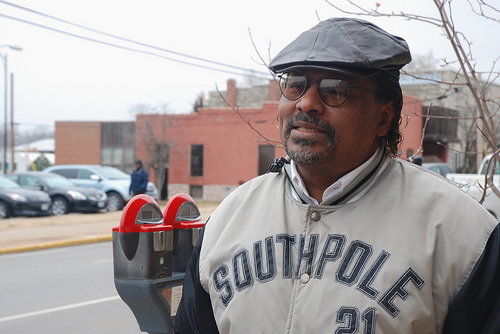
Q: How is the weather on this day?
A: It is clear.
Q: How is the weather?
A: It is clear.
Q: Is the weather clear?
A: Yes, it is clear.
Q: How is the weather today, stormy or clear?
A: It is clear.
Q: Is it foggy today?
A: No, it is clear.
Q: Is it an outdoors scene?
A: Yes, it is outdoors.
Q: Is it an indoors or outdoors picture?
A: It is outdoors.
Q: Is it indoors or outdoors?
A: It is outdoors.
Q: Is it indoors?
A: No, it is outdoors.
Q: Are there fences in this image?
A: No, there are no fences.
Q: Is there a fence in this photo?
A: No, there are no fences.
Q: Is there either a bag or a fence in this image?
A: No, there are no fences or bags.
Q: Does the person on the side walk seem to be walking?
A: Yes, the person is walking.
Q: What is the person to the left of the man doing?
A: The person is walking.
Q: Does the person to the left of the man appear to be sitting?
A: No, the person is walking.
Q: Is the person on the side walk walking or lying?
A: The person is walking.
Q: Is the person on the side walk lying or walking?
A: The person is walking.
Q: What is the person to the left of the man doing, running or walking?
A: The person is walking.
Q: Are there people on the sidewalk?
A: Yes, there is a person on the sidewalk.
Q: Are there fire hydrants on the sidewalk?
A: No, there is a person on the sidewalk.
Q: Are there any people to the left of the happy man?
A: Yes, there is a person to the left of the man.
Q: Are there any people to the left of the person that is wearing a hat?
A: Yes, there is a person to the left of the man.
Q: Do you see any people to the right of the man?
A: No, the person is to the left of the man.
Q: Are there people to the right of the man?
A: No, the person is to the left of the man.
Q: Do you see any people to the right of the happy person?
A: No, the person is to the left of the man.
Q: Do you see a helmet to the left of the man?
A: No, there is a person to the left of the man.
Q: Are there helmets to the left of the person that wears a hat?
A: No, there is a person to the left of the man.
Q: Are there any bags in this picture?
A: No, there are no bags.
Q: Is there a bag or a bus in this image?
A: No, there are no bags or buses.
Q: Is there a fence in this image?
A: No, there are no fences.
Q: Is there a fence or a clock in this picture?
A: No, there are no fences or clocks.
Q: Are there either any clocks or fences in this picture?
A: No, there are no fences or clocks.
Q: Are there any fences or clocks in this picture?
A: No, there are no fences or clocks.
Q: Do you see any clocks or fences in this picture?
A: No, there are no fences or clocks.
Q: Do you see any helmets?
A: No, there are no helmets.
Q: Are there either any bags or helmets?
A: No, there are no helmets or bags.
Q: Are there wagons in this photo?
A: No, there are no wagons.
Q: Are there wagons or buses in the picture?
A: No, there are no wagons or buses.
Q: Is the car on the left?
A: Yes, the car is on the left of the image.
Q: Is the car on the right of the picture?
A: No, the car is on the left of the image.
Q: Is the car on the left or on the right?
A: The car is on the left of the image.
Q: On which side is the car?
A: The car is on the left of the image.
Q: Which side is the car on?
A: The car is on the left of the image.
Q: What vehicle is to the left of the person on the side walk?
A: The vehicle is a car.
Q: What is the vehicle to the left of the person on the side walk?
A: The vehicle is a car.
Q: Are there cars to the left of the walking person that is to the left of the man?
A: Yes, there is a car to the left of the person.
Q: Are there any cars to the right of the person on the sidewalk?
A: No, the car is to the left of the person.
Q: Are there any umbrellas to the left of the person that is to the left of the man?
A: No, there is a car to the left of the person.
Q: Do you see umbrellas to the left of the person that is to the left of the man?
A: No, there is a car to the left of the person.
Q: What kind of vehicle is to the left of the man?
A: The vehicle is a car.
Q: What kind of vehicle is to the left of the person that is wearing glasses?
A: The vehicle is a car.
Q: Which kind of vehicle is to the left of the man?
A: The vehicle is a car.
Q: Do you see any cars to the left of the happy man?
A: Yes, there is a car to the left of the man.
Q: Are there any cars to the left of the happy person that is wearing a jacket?
A: Yes, there is a car to the left of the man.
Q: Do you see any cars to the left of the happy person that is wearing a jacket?
A: Yes, there is a car to the left of the man.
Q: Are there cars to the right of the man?
A: No, the car is to the left of the man.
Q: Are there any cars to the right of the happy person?
A: No, the car is to the left of the man.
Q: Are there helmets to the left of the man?
A: No, there is a car to the left of the man.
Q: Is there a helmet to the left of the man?
A: No, there is a car to the left of the man.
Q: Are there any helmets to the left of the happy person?
A: No, there is a car to the left of the man.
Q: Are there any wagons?
A: No, there are no wagons.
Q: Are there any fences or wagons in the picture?
A: No, there are no wagons or fences.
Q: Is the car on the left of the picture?
A: Yes, the car is on the left of the image.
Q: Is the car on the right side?
A: No, the car is on the left of the image.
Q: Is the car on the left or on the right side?
A: The car is on the left of the image.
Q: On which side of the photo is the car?
A: The car is on the left of the image.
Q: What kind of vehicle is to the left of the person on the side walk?
A: The vehicle is a car.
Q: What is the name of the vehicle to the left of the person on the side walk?
A: The vehicle is a car.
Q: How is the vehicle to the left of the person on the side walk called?
A: The vehicle is a car.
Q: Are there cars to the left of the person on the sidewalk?
A: Yes, there is a car to the left of the person.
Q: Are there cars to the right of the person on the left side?
A: No, the car is to the left of the person.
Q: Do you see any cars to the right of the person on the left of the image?
A: No, the car is to the left of the person.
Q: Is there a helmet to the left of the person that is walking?
A: No, there is a car to the left of the person.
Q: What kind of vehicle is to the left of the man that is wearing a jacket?
A: The vehicle is a car.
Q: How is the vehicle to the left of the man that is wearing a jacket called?
A: The vehicle is a car.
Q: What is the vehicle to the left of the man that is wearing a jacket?
A: The vehicle is a car.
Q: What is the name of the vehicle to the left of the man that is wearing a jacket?
A: The vehicle is a car.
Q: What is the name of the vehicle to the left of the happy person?
A: The vehicle is a car.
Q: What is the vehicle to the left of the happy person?
A: The vehicle is a car.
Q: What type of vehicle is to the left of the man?
A: The vehicle is a car.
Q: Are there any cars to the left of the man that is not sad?
A: Yes, there is a car to the left of the man.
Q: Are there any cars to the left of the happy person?
A: Yes, there is a car to the left of the man.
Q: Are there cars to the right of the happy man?
A: No, the car is to the left of the man.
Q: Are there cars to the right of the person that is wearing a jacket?
A: No, the car is to the left of the man.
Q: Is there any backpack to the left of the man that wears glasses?
A: No, there is a car to the left of the man.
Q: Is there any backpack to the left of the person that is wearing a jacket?
A: No, there is a car to the left of the man.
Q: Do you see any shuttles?
A: No, there are no shuttles.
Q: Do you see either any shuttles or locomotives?
A: No, there are no shuttles or locomotives.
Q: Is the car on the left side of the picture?
A: Yes, the car is on the left of the image.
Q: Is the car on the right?
A: No, the car is on the left of the image.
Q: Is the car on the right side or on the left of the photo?
A: The car is on the left of the image.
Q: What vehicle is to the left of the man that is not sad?
A: The vehicle is a car.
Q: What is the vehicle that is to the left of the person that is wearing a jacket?
A: The vehicle is a car.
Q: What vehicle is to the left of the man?
A: The vehicle is a car.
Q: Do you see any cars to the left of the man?
A: Yes, there is a car to the left of the man.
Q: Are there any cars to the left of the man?
A: Yes, there is a car to the left of the man.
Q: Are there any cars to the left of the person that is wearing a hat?
A: Yes, there is a car to the left of the man.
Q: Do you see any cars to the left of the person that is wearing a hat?
A: Yes, there is a car to the left of the man.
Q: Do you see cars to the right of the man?
A: No, the car is to the left of the man.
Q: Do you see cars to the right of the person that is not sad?
A: No, the car is to the left of the man.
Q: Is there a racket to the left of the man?
A: No, there is a car to the left of the man.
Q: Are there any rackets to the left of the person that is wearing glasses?
A: No, there is a car to the left of the man.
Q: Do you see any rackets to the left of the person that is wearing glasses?
A: No, there is a car to the left of the man.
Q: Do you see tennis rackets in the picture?
A: No, there are no tennis rackets.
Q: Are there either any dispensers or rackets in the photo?
A: No, there are no rackets or dispensers.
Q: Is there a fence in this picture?
A: No, there are no fences.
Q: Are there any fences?
A: No, there are no fences.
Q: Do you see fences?
A: No, there are no fences.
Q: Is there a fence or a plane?
A: No, there are no fences or airplanes.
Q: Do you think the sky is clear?
A: Yes, the sky is clear.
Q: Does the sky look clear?
A: Yes, the sky is clear.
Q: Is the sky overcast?
A: No, the sky is clear.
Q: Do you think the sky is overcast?
A: No, the sky is clear.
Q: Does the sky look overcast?
A: No, the sky is clear.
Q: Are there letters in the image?
A: Yes, there are letters.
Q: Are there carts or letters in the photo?
A: Yes, there are letters.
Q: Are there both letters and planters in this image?
A: No, there are letters but no planters.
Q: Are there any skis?
A: No, there are no skis.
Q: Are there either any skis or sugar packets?
A: No, there are no skis or sugar packets.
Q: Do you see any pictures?
A: No, there are no pictures.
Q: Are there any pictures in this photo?
A: No, there are no pictures.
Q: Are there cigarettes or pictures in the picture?
A: No, there are no pictures or cigarettes.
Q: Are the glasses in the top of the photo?
A: Yes, the glasses are in the top of the image.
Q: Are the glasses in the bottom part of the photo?
A: No, the glasses are in the top of the image.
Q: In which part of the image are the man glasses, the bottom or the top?
A: The glasses are in the top of the image.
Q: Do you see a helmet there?
A: No, there are no helmets.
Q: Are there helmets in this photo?
A: No, there are no helmets.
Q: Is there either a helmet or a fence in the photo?
A: No, there are no helmets or fences.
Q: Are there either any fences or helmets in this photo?
A: No, there are no helmets or fences.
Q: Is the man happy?
A: Yes, the man is happy.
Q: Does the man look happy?
A: Yes, the man is happy.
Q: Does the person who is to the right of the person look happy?
A: Yes, the man is happy.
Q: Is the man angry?
A: No, the man is happy.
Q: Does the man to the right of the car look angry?
A: No, the man is happy.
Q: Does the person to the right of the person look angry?
A: No, the man is happy.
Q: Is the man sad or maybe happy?
A: The man is happy.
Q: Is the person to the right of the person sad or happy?
A: The man is happy.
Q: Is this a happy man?
A: Yes, this is a happy man.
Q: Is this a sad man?
A: No, this is a happy man.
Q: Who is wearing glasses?
A: The man is wearing glasses.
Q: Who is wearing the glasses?
A: The man is wearing glasses.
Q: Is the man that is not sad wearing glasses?
A: Yes, the man is wearing glasses.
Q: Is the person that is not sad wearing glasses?
A: Yes, the man is wearing glasses.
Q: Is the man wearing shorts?
A: No, the man is wearing glasses.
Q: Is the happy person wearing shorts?
A: No, the man is wearing glasses.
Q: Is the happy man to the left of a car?
A: No, the man is to the right of a car.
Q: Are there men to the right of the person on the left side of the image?
A: Yes, there is a man to the right of the person.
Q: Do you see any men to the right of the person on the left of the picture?
A: Yes, there is a man to the right of the person.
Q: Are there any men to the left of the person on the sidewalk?
A: No, the man is to the right of the person.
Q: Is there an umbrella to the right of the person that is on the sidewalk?
A: No, there is a man to the right of the person.